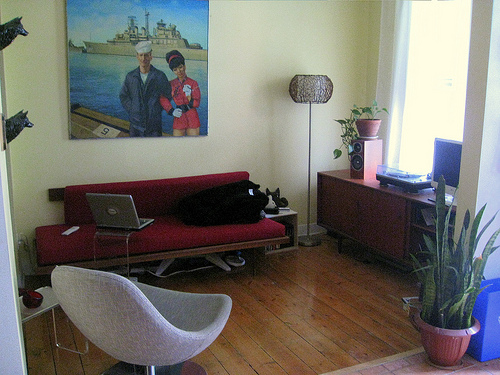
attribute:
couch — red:
[28, 167, 296, 284]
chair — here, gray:
[44, 252, 239, 374]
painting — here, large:
[46, 6, 221, 148]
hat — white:
[130, 34, 156, 59]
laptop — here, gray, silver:
[83, 181, 154, 235]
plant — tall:
[400, 180, 498, 336]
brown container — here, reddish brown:
[406, 314, 488, 369]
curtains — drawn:
[365, 1, 416, 170]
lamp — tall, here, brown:
[282, 66, 337, 252]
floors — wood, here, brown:
[211, 236, 422, 374]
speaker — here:
[345, 130, 385, 183]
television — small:
[425, 126, 474, 195]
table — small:
[19, 272, 104, 373]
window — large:
[390, 6, 476, 188]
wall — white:
[2, 4, 380, 196]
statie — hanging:
[0, 10, 35, 59]